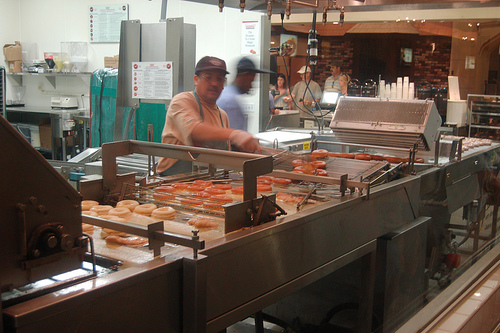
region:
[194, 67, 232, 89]
Man is wearing glasses.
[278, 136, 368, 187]
Doughnuts on the tray.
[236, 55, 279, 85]
Man is wearing a hat.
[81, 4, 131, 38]
Sign on the wall.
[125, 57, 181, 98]
Sign on the equipment.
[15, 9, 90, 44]
The wall is white.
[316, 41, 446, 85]
The entrance is brick.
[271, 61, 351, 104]
Customers in the background.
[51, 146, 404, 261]
A large amount of doughnuts.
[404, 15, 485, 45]
Lights on the ceiling.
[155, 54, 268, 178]
man behind counter making doughnuts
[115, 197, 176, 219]
row of glazed doughnuts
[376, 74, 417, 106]
stacks of white beverage cups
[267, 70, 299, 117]
female customer making order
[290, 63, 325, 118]
man with cap and gray shirt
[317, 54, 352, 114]
tall man standing at counter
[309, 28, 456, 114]
decorative brick wall in distance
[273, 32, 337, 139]
electrical wire to doughnut machine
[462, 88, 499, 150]
rack of silver trays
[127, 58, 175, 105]
rectangular sign on wall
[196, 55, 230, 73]
The man's black baseball hat.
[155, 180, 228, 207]
Several glazed donuts.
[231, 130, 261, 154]
A man's hand covered with a glove.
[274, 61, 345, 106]
Three people in the background.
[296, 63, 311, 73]
A man's white hat.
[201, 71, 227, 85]
The man's eye glasses.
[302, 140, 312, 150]
A small yellow label.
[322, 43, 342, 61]
Part of the wall.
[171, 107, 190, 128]
Part of the man's white shirt.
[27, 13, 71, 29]
Part of the white wall.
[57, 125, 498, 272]
Donuts are being made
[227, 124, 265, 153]
Man is wearing gloves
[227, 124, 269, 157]
Man is wearing white gloves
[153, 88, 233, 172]
Man is wearing a shirt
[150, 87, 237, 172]
Man is wearing a white shirt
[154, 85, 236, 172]
Man is wearing a t-shirt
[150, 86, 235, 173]
Man is wearing a white t-shirt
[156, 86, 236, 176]
Man is wearing an apron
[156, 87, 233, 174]
Man is wearing a blue apron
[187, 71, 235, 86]
Man is wearing glasses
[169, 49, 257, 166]
person standing behind donut conveyor belt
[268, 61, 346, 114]
three people standing in background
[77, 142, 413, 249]
doughnuts on conveyor belt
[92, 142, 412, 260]
doughnuts traveling down conveyor belt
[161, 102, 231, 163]
apron of man standing at conveyor belt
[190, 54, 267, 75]
hats of man behind conveyor belt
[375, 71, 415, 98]
stacks of white cups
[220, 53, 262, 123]
man standing with man wearing apron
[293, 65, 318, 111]
man wearing white hat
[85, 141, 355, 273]
rows of doughnuts